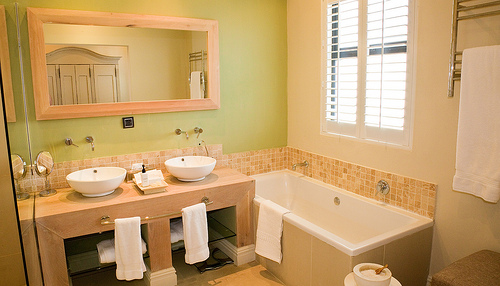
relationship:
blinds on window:
[317, 0, 414, 148] [329, 2, 406, 132]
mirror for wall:
[23, 3, 228, 123] [1, 4, 291, 154]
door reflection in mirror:
[45, 47, 120, 107] [36, 20, 210, 109]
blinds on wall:
[317, 0, 414, 148] [282, 2, 498, 174]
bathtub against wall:
[247, 169, 435, 286] [288, 2, 495, 280]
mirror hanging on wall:
[25, 7, 222, 121] [5, 0, 288, 163]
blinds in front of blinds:
[301, 0, 443, 148] [317, 0, 414, 148]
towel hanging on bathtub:
[250, 195, 291, 267] [248, 168, 434, 284]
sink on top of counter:
[164, 156, 216, 182] [24, 159, 251, 219]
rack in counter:
[90, 194, 237, 230] [38, 162, 260, 223]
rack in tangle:
[100, 197, 216, 226] [114, 216, 145, 281]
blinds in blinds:
[317, 0, 414, 148] [326, 37, 473, 144]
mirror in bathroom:
[25, 7, 222, 121] [1, 0, 498, 284]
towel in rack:
[183, 201, 210, 265] [99, 198, 220, 225]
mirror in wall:
[25, 7, 222, 121] [215, 26, 487, 228]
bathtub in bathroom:
[248, 168, 434, 284] [1, 0, 498, 284]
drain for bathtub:
[332, 195, 342, 204] [247, 169, 435, 286]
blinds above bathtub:
[317, 0, 414, 148] [259, 171, 382, 224]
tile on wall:
[30, 147, 449, 260] [276, 9, 470, 242]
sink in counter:
[160, 153, 217, 183] [10, 163, 258, 283]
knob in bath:
[375, 176, 391, 196] [5, 4, 492, 281]